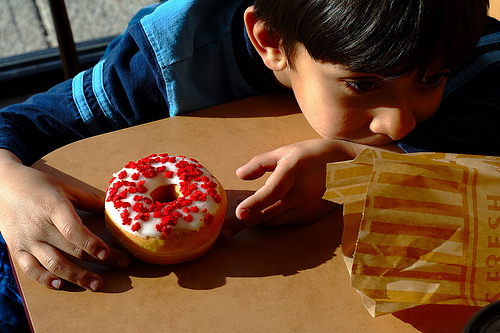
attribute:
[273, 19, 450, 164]
face — white, smooth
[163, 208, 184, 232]
sprinkle — red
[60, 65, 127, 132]
stripes — little, blue, dark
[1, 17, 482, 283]
shirt — blue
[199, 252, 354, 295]
shadow — dark, black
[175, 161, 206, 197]
sprinkle — red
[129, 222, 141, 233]
sprinkle — red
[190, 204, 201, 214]
sprinkle — red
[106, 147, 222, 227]
sprinkle — red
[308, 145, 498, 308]
bag — paper, open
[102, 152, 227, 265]
donut — plain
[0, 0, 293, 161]
shirt — blue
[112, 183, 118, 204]
sprinkle — red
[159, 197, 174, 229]
sprinkle — red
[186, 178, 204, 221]
sprinkle — red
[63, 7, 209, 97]
shirt — blue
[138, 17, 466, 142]
boy — little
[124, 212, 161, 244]
frosting — white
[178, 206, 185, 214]
sprinkle — red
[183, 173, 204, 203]
sprinkle — red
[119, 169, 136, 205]
sprinkle — red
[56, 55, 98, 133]
stripes — light, blue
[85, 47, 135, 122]
stripes — light, blue